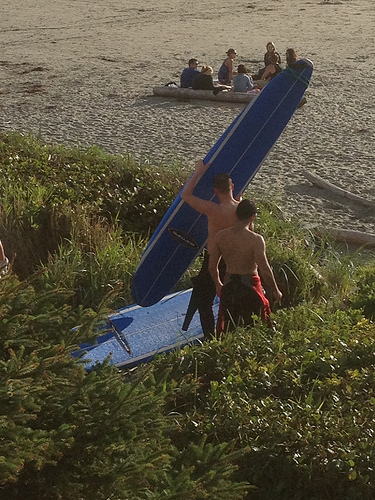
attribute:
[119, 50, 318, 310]
board — blue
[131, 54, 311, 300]
surfboard — long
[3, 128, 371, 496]
grass — tall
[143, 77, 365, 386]
surfboard — long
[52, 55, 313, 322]
surfboard — long, blue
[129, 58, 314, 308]
board — blue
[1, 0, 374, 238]
beach — sandy 